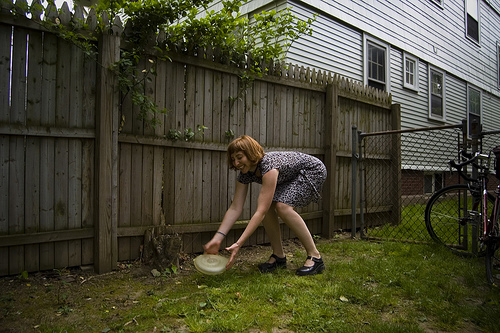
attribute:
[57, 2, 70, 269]
wood — small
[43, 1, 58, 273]
wood — small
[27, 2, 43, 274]
wood — small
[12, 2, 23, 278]
wood — brown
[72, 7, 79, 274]
wood — brown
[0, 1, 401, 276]
fence — wooden, picket, brown, wood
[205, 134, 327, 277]
woman — bending over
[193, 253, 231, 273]
frisbee — white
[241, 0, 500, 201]
house — brick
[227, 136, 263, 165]
hair — red, short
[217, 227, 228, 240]
bracelet — black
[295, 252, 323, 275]
shoe — black, mary jane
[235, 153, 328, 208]
dress — floral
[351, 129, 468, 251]
gate — metal, rusty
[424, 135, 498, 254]
bike — parked, red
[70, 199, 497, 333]
grass — green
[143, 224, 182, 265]
back pack — camo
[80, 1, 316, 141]
tree — green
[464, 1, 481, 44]
window — open